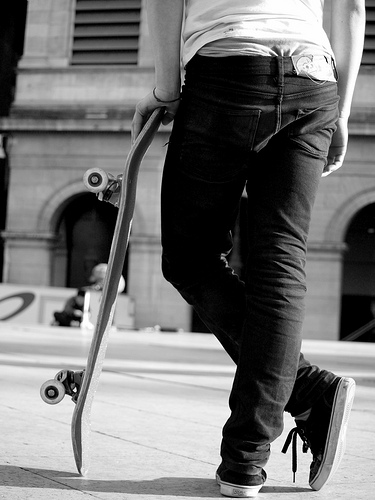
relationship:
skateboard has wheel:
[38, 105, 170, 475] [85, 165, 110, 200]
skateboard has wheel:
[38, 105, 170, 475] [41, 376, 67, 407]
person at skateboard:
[129, 0, 366, 495] [38, 105, 170, 475]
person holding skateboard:
[129, 0, 366, 495] [38, 105, 170, 475]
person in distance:
[72, 256, 130, 330] [0, 206, 359, 337]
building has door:
[6, 0, 373, 371] [53, 193, 129, 300]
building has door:
[6, 0, 373, 371] [339, 204, 374, 343]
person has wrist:
[129, 0, 366, 495] [148, 81, 191, 107]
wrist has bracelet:
[148, 81, 191, 107] [149, 89, 183, 107]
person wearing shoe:
[129, 0, 366, 495] [295, 374, 352, 492]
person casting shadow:
[129, 0, 366, 495] [0, 457, 229, 496]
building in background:
[6, 0, 373, 371] [0, 4, 369, 328]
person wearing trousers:
[129, 0, 366, 495] [156, 52, 342, 473]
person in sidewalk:
[129, 0, 366, 495] [6, 345, 374, 499]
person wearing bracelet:
[129, 0, 366, 495] [149, 89, 183, 107]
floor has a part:
[6, 345, 374, 499] [127, 380, 177, 452]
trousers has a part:
[156, 52, 342, 473] [300, 96, 306, 186]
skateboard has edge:
[38, 105, 170, 475] [71, 101, 159, 462]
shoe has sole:
[295, 374, 352, 492] [311, 375, 352, 488]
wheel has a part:
[85, 165, 110, 200] [92, 173, 98, 187]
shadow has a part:
[0, 457, 229, 496] [177, 479, 192, 487]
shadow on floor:
[0, 457, 229, 496] [6, 345, 374, 499]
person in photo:
[129, 0, 366, 495] [9, 1, 374, 499]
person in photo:
[72, 256, 130, 330] [9, 1, 374, 499]